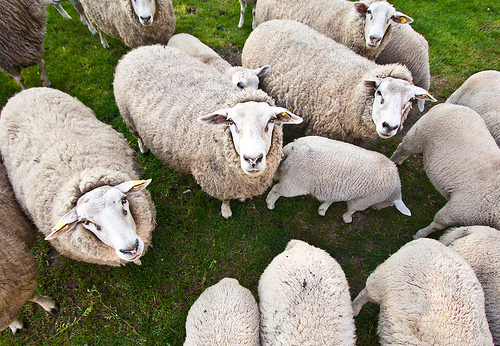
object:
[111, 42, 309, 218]
sheep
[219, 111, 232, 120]
tag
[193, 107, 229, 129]
ear